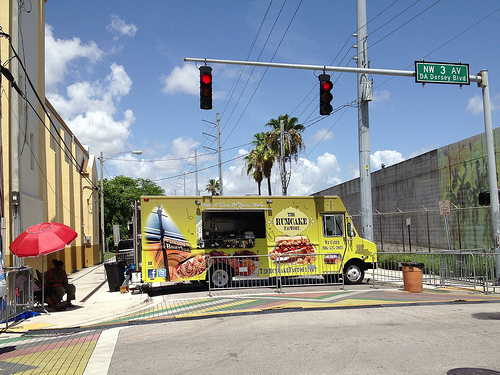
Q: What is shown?
A: Food truck.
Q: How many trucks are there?
A: 1.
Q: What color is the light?
A: Red.